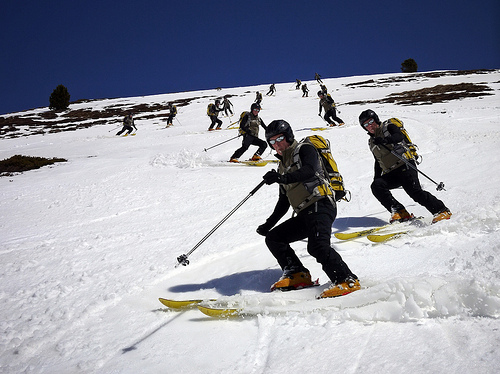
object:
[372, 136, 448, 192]
ski pole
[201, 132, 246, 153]
ski pole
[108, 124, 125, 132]
ski pole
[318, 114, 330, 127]
ski pole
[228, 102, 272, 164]
person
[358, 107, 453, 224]
man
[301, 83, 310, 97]
man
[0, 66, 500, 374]
hill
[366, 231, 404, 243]
yellow ski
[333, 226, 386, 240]
yellow ski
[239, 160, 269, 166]
yellow ski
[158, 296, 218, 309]
yellow ski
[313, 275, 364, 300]
shoes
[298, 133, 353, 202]
backpack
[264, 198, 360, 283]
pants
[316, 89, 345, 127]
person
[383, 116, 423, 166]
backpack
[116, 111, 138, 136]
man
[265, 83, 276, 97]
people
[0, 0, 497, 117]
blue sky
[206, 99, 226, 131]
person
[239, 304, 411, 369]
snow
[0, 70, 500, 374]
ground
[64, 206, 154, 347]
snow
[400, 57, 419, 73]
tree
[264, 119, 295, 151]
helmet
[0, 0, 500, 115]
sky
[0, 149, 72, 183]
snow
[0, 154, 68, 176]
grass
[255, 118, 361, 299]
man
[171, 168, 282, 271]
pole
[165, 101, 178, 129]
person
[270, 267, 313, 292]
boots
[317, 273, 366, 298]
feet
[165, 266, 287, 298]
shadow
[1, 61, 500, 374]
snow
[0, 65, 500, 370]
ski slope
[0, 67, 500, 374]
mountain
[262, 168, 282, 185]
hand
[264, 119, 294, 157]
head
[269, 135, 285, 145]
ski glasses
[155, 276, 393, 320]
skiing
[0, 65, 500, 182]
background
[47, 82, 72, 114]
tree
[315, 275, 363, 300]
snow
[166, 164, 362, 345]
angle